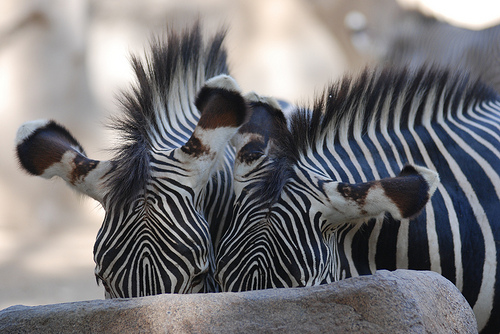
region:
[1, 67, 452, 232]
four ears from zebra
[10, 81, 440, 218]
black and white ears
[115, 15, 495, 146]
two black and white manes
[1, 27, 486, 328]
two zebras eating together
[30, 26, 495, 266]
two black and white zebra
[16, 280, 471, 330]
a stone in front of zebra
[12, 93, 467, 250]
four ears on two heads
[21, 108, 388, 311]
two heads of zebra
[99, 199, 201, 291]
black stripes on head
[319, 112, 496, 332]
black stripes on body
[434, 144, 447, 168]
black stripe on a zebra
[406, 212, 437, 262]
black stripe on a zebra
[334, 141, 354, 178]
black stripe on a zebra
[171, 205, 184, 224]
black stripe on a zebra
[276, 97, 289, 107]
black stripe on a zebra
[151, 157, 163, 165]
black stripe on a zebra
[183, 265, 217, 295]
a black eye on a head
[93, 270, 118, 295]
a black eye on head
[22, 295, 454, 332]
a large gray stone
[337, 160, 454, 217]
a pointy black and white ear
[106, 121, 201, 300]
black and white fur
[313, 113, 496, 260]
black and white fur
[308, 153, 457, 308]
black and white fur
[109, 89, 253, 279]
black and white fur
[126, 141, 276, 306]
zebra's fur is stripes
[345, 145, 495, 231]
zebra's fur is stripes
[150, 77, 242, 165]
zebra's fur is stripes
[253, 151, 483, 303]
zebra's fur is stripes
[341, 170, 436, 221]
a zebras ear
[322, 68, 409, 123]
a zebras hair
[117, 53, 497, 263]
the zebra is black and white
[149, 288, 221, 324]
light on the rock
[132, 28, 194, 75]
hair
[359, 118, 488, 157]
zebra has black stripes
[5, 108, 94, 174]
zebra ear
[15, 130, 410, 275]
two zebras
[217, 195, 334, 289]
zebras head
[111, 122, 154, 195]
zebras hair on head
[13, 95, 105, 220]
The right ear of the zebra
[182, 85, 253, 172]
The left ear of the zebra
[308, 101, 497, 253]
The zebra is black and white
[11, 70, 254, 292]
The head of the zebra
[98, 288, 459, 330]
The rock is the color gray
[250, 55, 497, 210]
The mane of the zebra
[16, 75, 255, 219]
Half of the head of the zebra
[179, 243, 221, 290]
The left eye of the zebra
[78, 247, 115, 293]
The right ear of the zebra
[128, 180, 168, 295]
The middle of the zebra's head